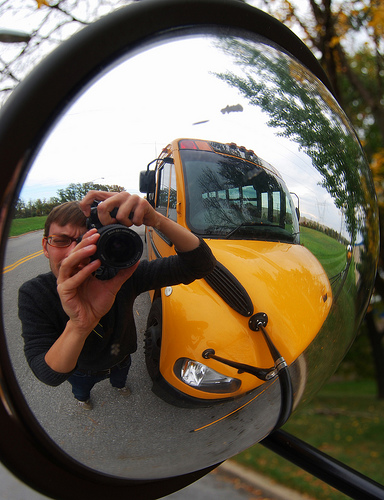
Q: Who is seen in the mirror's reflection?
A: Man taking photograph.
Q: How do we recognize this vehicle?
A: School buses are always yellow.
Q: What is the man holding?
A: A camera.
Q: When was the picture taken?
A: During the daytime.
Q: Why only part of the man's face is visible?
A: It's obstructed by the camera.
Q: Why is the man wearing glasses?
A: To correct the vision.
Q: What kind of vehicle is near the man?
A: A school bus.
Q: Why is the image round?
A: It's the mirror reflection.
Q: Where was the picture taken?
A: On a road.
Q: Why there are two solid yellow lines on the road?
A: To indicate no passing zone between two lanes.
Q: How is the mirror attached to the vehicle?
A: By a black metal arm.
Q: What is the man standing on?
A: The road.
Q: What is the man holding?
A: Camera.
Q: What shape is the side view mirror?
A: Round.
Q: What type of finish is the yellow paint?
A: Gloss.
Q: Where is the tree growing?
A: On the side of the road.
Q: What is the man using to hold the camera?
A: Hands.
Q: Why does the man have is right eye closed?
A: He is focusing the camera.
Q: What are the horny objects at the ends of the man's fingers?
A: Nails.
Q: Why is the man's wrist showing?
A: He has the sleeve pulled up.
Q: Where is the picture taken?
A: A street.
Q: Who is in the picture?
A: A man.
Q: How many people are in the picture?
A: One.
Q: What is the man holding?
A: A camera.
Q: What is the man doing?
A: Taking a picture.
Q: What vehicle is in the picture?
A: A bus.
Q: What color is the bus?
A: Yellow.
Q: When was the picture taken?
A: Daytime.